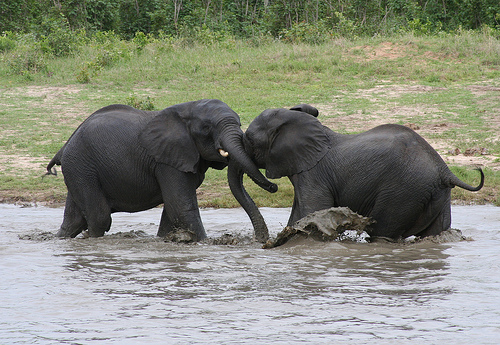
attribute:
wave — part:
[336, 281, 451, 295]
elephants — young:
[44, 88, 489, 252]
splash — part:
[283, 209, 375, 246]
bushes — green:
[0, 0, 495, 35]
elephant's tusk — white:
[218, 148, 229, 157]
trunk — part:
[213, 125, 278, 191]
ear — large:
[136, 103, 199, 174]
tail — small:
[445, 163, 485, 193]